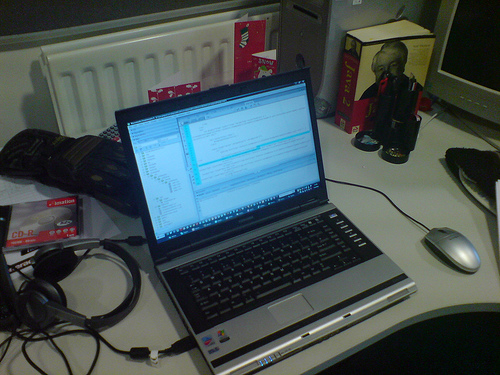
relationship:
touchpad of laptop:
[264, 293, 313, 330] [115, 69, 415, 374]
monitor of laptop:
[115, 69, 328, 260] [115, 69, 415, 374]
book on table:
[332, 21, 437, 135] [2, 104, 498, 373]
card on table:
[250, 48, 278, 83] [2, 104, 498, 373]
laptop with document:
[115, 69, 415, 374] [128, 83, 322, 241]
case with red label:
[1, 193, 79, 254] [6, 195, 80, 247]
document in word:
[128, 83, 322, 241] [115, 69, 328, 260]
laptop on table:
[115, 69, 415, 374] [2, 104, 498, 373]